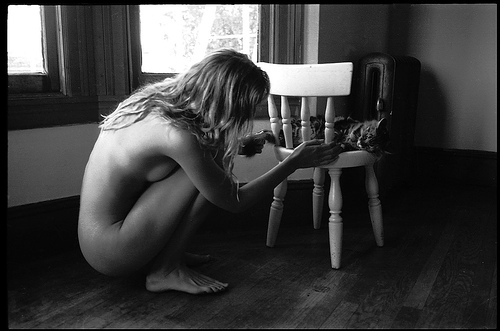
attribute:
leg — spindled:
[325, 165, 346, 270]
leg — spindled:
[364, 163, 384, 245]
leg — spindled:
[310, 164, 326, 227]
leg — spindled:
[264, 174, 287, 246]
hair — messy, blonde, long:
[133, 50, 261, 177]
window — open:
[139, 3, 259, 73]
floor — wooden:
[395, 247, 485, 312]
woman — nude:
[51, 57, 328, 321]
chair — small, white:
[233, 55, 450, 289]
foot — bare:
[138, 257, 236, 303]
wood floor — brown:
[8, 167, 495, 329]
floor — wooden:
[228, 241, 497, 329]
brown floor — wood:
[0, 260, 500, 329]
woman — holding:
[64, 47, 347, 299]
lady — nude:
[74, 55, 339, 297]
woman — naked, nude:
[73, 52, 335, 293]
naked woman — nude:
[78, 45, 339, 302]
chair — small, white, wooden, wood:
[254, 54, 391, 271]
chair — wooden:
[249, 47, 397, 255]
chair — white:
[244, 46, 398, 278]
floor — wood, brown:
[13, 199, 498, 329]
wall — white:
[10, 125, 325, 212]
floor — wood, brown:
[372, 242, 452, 302]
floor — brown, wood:
[23, 158, 495, 329]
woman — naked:
[82, 65, 281, 292]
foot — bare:
[144, 251, 229, 304]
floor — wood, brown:
[102, 236, 473, 313]